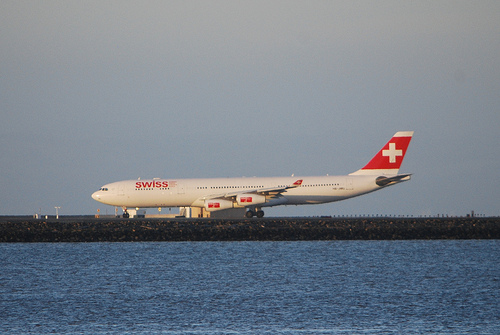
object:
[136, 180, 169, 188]
letter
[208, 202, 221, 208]
decal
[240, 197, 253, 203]
decal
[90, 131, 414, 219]
airliner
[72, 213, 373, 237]
tarmac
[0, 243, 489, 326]
water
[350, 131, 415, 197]
tail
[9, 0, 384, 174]
sky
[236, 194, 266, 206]
engine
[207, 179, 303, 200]
wing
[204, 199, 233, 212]
engine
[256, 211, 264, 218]
gear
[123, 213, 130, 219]
gear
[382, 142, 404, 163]
cross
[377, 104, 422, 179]
background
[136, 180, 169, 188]
swiss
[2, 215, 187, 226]
runway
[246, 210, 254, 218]
part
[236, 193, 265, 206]
part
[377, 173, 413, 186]
part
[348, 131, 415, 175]
part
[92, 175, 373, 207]
part